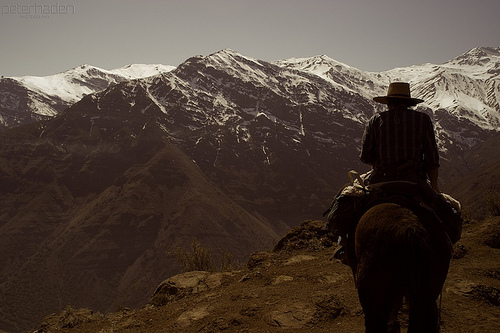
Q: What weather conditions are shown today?
A: It is clear.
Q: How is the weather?
A: It is clear.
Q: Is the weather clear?
A: Yes, it is clear.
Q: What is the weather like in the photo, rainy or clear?
A: It is clear.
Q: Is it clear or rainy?
A: It is clear.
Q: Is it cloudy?
A: No, it is clear.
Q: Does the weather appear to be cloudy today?
A: No, it is clear.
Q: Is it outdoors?
A: Yes, it is outdoors.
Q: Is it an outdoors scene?
A: Yes, it is outdoors.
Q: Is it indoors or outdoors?
A: It is outdoors.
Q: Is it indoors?
A: No, it is outdoors.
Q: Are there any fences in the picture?
A: No, there are no fences.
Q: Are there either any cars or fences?
A: No, there are no fences or cars.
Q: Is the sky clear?
A: Yes, the sky is clear.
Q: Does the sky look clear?
A: Yes, the sky is clear.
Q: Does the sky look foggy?
A: No, the sky is clear.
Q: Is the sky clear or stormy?
A: The sky is clear.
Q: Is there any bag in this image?
A: Yes, there is a bag.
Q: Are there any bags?
A: Yes, there is a bag.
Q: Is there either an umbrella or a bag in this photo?
A: Yes, there is a bag.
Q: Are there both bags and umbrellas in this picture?
A: No, there is a bag but no umbrellas.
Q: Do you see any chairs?
A: No, there are no chairs.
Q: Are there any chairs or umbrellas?
A: No, there are no chairs or umbrellas.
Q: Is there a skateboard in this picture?
A: No, there are no skateboards.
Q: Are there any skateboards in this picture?
A: No, there are no skateboards.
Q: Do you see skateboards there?
A: No, there are no skateboards.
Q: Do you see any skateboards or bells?
A: No, there are no skateboards or bells.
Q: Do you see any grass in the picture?
A: Yes, there is grass.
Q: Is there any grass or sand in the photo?
A: Yes, there is grass.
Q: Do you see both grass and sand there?
A: No, there is grass but no sand.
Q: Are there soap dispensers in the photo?
A: No, there are no soap dispensers.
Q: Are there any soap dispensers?
A: No, there are no soap dispensers.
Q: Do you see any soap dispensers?
A: No, there are no soap dispensers.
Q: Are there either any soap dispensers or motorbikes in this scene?
A: No, there are no soap dispensers or motorbikes.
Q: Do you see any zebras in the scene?
A: No, there are no zebras.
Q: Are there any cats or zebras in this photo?
A: No, there are no zebras or cats.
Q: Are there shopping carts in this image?
A: No, there are no shopping carts.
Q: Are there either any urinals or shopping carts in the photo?
A: No, there are no shopping carts or urinals.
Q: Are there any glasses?
A: No, there are no glasses.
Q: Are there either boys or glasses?
A: No, there are no glasses or boys.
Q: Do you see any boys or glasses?
A: No, there are no glasses or boys.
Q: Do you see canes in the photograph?
A: No, there are no canes.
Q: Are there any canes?
A: No, there are no canes.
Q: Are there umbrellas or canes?
A: No, there are no canes or umbrellas.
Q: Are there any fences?
A: No, there are no fences.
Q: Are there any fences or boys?
A: No, there are no fences or boys.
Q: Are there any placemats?
A: No, there are no placemats.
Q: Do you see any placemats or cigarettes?
A: No, there are no placemats or cigarettes.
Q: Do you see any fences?
A: No, there are no fences.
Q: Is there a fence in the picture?
A: No, there are no fences.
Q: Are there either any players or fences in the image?
A: No, there are no fences or players.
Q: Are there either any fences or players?
A: No, there are no fences or players.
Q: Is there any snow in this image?
A: Yes, there is snow.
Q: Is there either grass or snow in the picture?
A: Yes, there is snow.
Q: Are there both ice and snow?
A: No, there is snow but no ice.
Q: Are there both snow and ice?
A: No, there is snow but no ice.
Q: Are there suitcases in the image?
A: No, there are no suitcases.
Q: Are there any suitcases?
A: No, there are no suitcases.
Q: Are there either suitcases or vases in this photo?
A: No, there are no suitcases or vases.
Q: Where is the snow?
A: The snow is on the mountain.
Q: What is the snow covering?
A: The snow is covering the mountain.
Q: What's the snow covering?
A: The snow is covering the mountain.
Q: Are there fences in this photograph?
A: No, there are no fences.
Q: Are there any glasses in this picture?
A: No, there are no glasses.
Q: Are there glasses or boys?
A: No, there are no glasses or boys.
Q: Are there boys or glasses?
A: No, there are no glasses or boys.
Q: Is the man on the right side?
A: Yes, the man is on the right of the image.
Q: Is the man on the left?
A: No, the man is on the right of the image.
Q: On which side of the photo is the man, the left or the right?
A: The man is on the right of the image.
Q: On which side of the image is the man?
A: The man is on the right of the image.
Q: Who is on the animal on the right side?
A: The man is on the horse.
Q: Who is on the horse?
A: The man is on the horse.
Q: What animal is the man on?
A: The man is on the horse.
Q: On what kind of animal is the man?
A: The man is on the horse.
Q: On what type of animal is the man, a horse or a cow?
A: The man is on a horse.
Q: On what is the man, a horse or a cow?
A: The man is on a horse.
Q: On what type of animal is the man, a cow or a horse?
A: The man is on a horse.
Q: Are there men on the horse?
A: Yes, there is a man on the horse.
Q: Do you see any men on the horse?
A: Yes, there is a man on the horse.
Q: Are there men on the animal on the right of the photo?
A: Yes, there is a man on the horse.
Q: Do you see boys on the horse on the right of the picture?
A: No, there is a man on the horse.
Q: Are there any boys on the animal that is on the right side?
A: No, there is a man on the horse.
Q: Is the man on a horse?
A: Yes, the man is on a horse.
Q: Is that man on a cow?
A: No, the man is on a horse.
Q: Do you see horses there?
A: Yes, there is a horse.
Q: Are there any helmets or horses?
A: Yes, there is a horse.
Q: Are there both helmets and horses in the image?
A: No, there is a horse but no helmets.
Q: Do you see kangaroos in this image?
A: No, there are no kangaroos.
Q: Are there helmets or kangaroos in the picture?
A: No, there are no kangaroos or helmets.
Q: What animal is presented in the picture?
A: The animal is a horse.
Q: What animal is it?
A: The animal is a horse.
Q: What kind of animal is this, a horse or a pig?
A: That is a horse.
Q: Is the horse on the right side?
A: Yes, the horse is on the right of the image.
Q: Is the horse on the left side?
A: No, the horse is on the right of the image.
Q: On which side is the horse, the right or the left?
A: The horse is on the right of the image.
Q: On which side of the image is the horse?
A: The horse is on the right of the image.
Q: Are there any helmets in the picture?
A: No, there are no helmets.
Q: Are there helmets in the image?
A: No, there are no helmets.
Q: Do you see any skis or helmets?
A: No, there are no helmets or skis.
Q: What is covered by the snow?
A: The mountain is covered by the snow.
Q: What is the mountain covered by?
A: The mountain is covered by the snow.